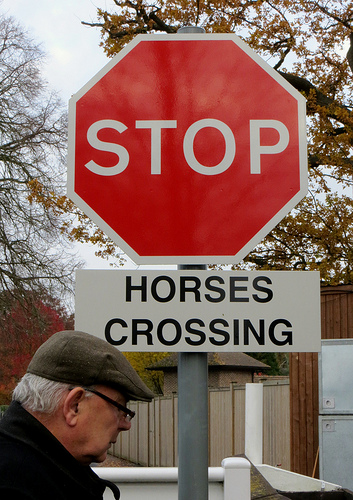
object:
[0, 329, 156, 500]
man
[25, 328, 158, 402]
hat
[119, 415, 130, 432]
nose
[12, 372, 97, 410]
hair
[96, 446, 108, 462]
chin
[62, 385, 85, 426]
ear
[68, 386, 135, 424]
glasses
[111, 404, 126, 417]
eye